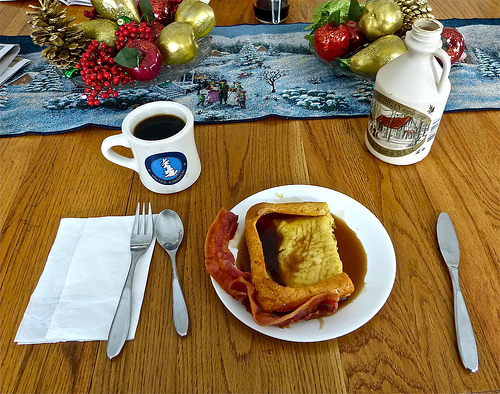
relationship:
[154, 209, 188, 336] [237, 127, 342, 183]
spoon on table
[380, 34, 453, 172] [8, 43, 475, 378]
bottle on table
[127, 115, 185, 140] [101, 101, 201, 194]
coffee in cup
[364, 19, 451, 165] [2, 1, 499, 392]
bottle on table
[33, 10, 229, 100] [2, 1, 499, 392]
centerpiece on table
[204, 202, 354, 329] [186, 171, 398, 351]
bacon on plate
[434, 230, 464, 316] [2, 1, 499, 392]
knife on a table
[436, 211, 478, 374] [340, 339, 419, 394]
knife on a table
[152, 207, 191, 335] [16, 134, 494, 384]
spoon on a table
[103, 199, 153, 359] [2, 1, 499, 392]
fork on a table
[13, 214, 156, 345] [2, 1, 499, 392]
napkin on a table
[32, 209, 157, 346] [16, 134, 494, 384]
napkin on a table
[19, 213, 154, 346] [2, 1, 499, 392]
napkin on a table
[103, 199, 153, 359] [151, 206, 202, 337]
fork and spoon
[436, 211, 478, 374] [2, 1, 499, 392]
knife on table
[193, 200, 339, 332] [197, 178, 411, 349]
bacon on plate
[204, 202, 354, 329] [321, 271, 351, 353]
bacon on plate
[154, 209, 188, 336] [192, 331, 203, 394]
spoon on table